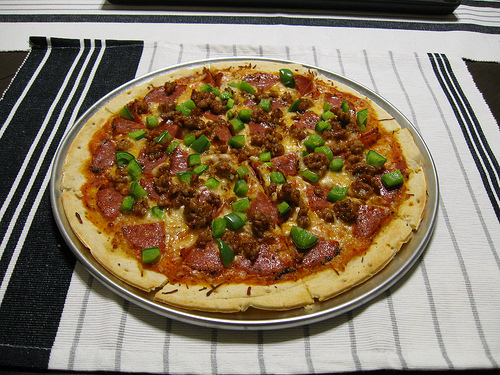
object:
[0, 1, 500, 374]
tablecloth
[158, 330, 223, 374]
pattern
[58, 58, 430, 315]
pizza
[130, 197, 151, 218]
meat